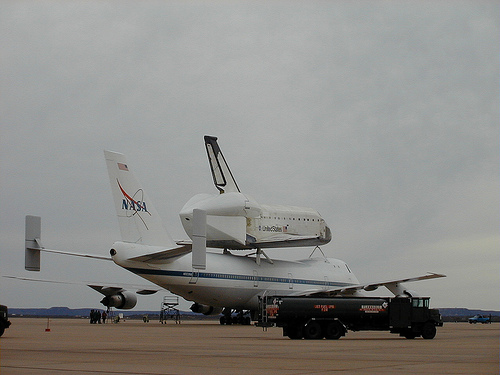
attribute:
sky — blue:
[373, 169, 451, 266]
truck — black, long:
[277, 290, 453, 345]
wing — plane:
[287, 268, 454, 293]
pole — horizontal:
[19, 209, 76, 301]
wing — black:
[200, 132, 240, 189]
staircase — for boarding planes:
[136, 291, 181, 317]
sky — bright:
[4, 3, 499, 312]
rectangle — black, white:
[205, 140, 227, 188]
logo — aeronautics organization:
[118, 170, 134, 227]